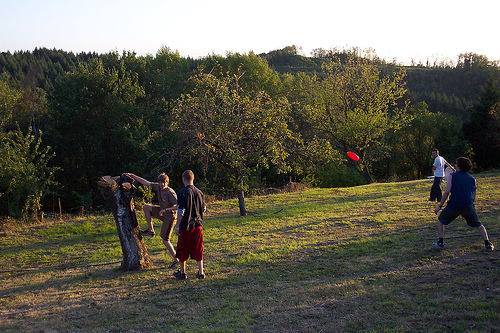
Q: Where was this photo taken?
A: In a field.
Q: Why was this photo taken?
A: To capture the sport and the player.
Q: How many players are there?
A: There are 4.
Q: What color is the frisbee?
A: It is red.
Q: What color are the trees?
A: They are green.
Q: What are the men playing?
A: They are playing frisbee.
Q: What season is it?
A: Autumn.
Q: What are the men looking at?
A: A frisbee.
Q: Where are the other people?
A: By the tree trunk.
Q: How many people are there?
A: Four.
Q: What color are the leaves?
A: Green.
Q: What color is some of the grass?
A: Brown.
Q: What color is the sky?
A: Blue and gray.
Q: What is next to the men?
A: Trees.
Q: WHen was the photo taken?
A: In the late afternoon.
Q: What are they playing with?
A: A red frisbee.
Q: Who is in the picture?
A: Four males.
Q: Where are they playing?
A: In a field.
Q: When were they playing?
A: In the summer.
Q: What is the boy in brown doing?
A: Climbing the tree stump.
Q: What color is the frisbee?
A: Red.